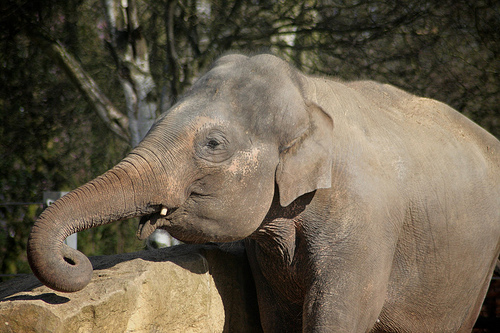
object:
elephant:
[23, 52, 499, 332]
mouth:
[134, 204, 173, 243]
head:
[25, 50, 315, 313]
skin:
[25, 50, 498, 330]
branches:
[170, 0, 179, 106]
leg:
[300, 283, 387, 332]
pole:
[40, 188, 79, 256]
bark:
[49, 0, 323, 248]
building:
[0, 0, 497, 275]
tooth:
[160, 205, 168, 218]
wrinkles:
[128, 139, 174, 148]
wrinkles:
[188, 159, 249, 168]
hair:
[204, 50, 287, 77]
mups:
[212, 44, 294, 81]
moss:
[64, 24, 126, 160]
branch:
[48, 38, 138, 138]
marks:
[227, 148, 255, 178]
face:
[143, 76, 281, 240]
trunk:
[12, 137, 195, 291]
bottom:
[39, 234, 94, 286]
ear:
[274, 108, 336, 205]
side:
[201, 73, 322, 223]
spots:
[163, 175, 185, 195]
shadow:
[159, 225, 322, 329]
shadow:
[0, 289, 75, 307]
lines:
[139, 136, 176, 142]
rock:
[4, 239, 232, 331]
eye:
[193, 122, 240, 166]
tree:
[0, 10, 500, 282]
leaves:
[66, 93, 80, 101]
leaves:
[396, 40, 404, 43]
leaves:
[354, 24, 360, 27]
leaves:
[372, 14, 386, 24]